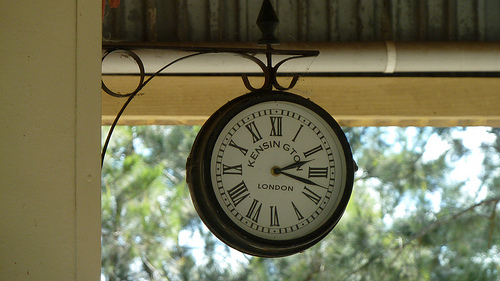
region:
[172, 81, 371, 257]
The clock has roman numerals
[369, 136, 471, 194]
Leaves in the background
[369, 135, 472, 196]
Green leaves in the background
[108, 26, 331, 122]
Structure holding the clock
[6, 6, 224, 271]
Wall near the clock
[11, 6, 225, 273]
White wall near the clock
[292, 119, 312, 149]
number on a clock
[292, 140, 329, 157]
number on a clock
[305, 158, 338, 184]
number on a clock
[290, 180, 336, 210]
number on a clock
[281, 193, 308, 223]
number on a clock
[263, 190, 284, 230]
number on a clock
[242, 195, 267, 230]
number on a clock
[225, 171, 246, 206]
number on a clock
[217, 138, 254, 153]
number on a clock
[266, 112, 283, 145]
number on a clock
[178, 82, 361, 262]
a clock hanging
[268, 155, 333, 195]
long and short hand of the clock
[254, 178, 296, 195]
a LONDON word on the clock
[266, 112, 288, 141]
Roman Numeral twelve on the clock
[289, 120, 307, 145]
Roman Numeral one on the clock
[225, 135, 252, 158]
Roman Numeral ten on the clock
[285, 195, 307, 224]
Roman Numeral five on the clock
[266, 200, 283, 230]
Roman Numeral six on the clock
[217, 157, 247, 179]
Roman Numeral nine on the clock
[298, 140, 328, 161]
Roman Numeral two on the clock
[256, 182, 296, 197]
London is on the clock.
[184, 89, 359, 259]
A clock is hanging by the wall.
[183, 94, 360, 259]
The clock has Roman numerals.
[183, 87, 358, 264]
The clock is black.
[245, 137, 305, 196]
The clock says Kensington London.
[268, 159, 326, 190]
The clock hands are black.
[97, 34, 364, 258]
The clock is attached to the wall.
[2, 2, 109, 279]
The wall is white.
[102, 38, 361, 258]
The clock is made of metal.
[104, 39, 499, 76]
A white pipe is against the wall.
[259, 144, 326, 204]
Hands on a clock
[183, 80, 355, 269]
Face on a clock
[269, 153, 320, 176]
Little hand on a clock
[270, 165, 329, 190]
Big hand on a clock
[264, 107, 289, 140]
XII on a clock face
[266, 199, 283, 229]
VI on a clock face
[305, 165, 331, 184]
III on a clock face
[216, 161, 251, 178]
IX on a clock face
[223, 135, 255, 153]
X on a clock face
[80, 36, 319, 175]
Metal clock display arm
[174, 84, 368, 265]
the clock is color white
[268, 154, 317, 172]
small hour handle of clock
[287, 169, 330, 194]
large minute handle of clock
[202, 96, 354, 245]
clock has roman numerals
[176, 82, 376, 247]
The hanging clock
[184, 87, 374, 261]
A hanging clock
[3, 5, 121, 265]
The piece of wall to the left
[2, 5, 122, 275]
A piece of wall to the left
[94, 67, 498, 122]
The wood beam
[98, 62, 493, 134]
A wood beam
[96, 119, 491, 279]
The forest area in the background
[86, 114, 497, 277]
A forest area in the background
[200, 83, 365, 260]
a clock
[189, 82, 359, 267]
brown and white clock